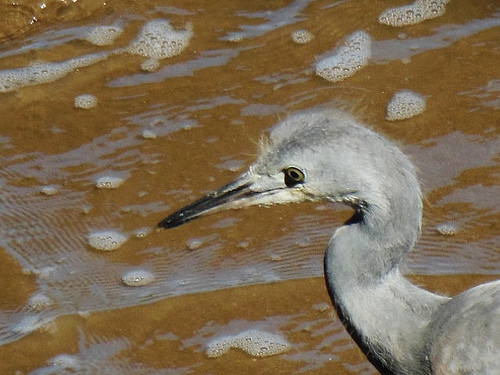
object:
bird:
[155, 102, 499, 372]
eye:
[281, 165, 310, 185]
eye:
[283, 165, 305, 186]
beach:
[2, 1, 499, 373]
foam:
[211, 331, 287, 352]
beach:
[86, 251, 151, 323]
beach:
[107, 291, 182, 339]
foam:
[87, 218, 148, 265]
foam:
[31, 162, 126, 201]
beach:
[41, 224, 125, 309]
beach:
[85, 76, 135, 116]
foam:
[117, 29, 184, 60]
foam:
[125, 25, 197, 72]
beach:
[106, 81, 162, 137]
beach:
[174, 50, 252, 104]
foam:
[123, 12, 186, 61]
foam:
[367, 71, 438, 139]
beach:
[97, 119, 173, 164]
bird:
[225, 76, 433, 366]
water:
[39, 168, 165, 324]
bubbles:
[65, 141, 121, 279]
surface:
[37, 170, 151, 312]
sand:
[64, 159, 106, 240]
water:
[87, 256, 195, 331]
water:
[161, 305, 204, 329]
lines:
[18, 230, 108, 317]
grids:
[50, 242, 150, 305]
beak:
[164, 189, 257, 233]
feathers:
[275, 91, 410, 230]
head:
[229, 110, 407, 255]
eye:
[287, 163, 307, 190]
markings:
[383, 289, 478, 365]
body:
[313, 209, 498, 366]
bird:
[218, 81, 488, 370]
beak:
[171, 174, 280, 237]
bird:
[211, 110, 457, 370]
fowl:
[190, 95, 437, 340]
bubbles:
[127, 29, 184, 54]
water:
[139, 56, 190, 108]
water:
[107, 272, 206, 326]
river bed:
[56, 192, 147, 324]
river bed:
[94, 286, 226, 372]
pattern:
[17, 209, 120, 296]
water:
[93, 299, 177, 343]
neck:
[325, 197, 430, 355]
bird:
[145, 90, 493, 364]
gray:
[437, 306, 456, 322]